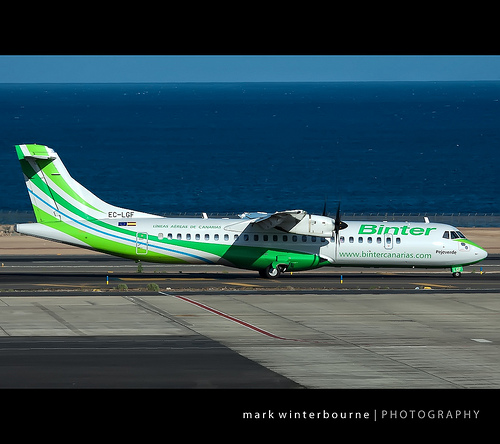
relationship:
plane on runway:
[8, 135, 487, 287] [5, 257, 477, 295]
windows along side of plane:
[152, 223, 403, 251] [8, 135, 487, 287]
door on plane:
[129, 228, 157, 257] [8, 135, 487, 287]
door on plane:
[381, 227, 397, 252] [0, 110, 482, 272]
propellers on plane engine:
[315, 195, 345, 240] [319, 210, 352, 237]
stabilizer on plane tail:
[17, 151, 57, 165] [0, 142, 165, 222]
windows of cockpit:
[434, 224, 464, 239] [425, 215, 484, 271]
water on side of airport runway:
[7, 82, 499, 219] [455, 226, 484, 251]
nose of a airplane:
[467, 239, 484, 269] [3, 135, 474, 279]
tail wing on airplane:
[4, 136, 170, 222] [3, 135, 474, 279]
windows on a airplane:
[148, 229, 406, 245] [3, 135, 474, 279]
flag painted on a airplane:
[113, 217, 140, 229] [3, 135, 474, 279]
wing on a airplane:
[239, 201, 307, 237] [3, 135, 474, 279]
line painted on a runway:
[160, 287, 284, 338] [2, 296, 484, 358]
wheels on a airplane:
[257, 266, 284, 277] [3, 135, 474, 279]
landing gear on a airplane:
[444, 265, 473, 280] [3, 135, 474, 279]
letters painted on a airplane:
[354, 220, 439, 240] [3, 135, 474, 279]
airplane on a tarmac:
[3, 135, 474, 279] [2, 260, 482, 335]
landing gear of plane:
[254, 264, 288, 278] [0, 131, 480, 279]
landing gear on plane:
[447, 263, 468, 282] [8, 135, 487, 287]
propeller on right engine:
[331, 193, 345, 243] [298, 206, 348, 238]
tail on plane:
[14, 133, 137, 216] [8, 135, 487, 287]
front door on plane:
[383, 227, 393, 250] [8, 135, 487, 287]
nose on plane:
[456, 232, 487, 273] [7, 136, 486, 269]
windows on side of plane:
[368, 232, 402, 248] [8, 135, 487, 287]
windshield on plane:
[449, 230, 463, 241] [7, 136, 486, 269]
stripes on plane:
[24, 145, 321, 277] [8, 135, 487, 287]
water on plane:
[1, 81, 498, 234] [7, 136, 486, 269]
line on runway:
[160, 287, 284, 338] [5, 292, 499, 386]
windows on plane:
[2, 139, 491, 287] [157, 229, 406, 245]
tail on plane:
[10, 137, 160, 218] [8, 135, 487, 287]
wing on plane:
[248, 209, 312, 236] [7, 136, 486, 269]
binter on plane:
[358, 220, 437, 244] [8, 135, 487, 287]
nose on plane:
[456, 232, 487, 273] [8, 135, 487, 287]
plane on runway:
[8, 135, 487, 287] [0, 254, 497, 370]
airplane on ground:
[3, 135, 474, 279] [6, 227, 493, 393]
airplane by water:
[3, 135, 474, 279] [7, 82, 499, 219]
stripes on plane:
[5, 131, 319, 273] [8, 135, 487, 287]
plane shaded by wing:
[8, 135, 487, 287] [248, 203, 309, 231]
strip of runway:
[9, 258, 499, 297] [7, 254, 499, 383]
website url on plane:
[335, 247, 435, 264] [8, 135, 487, 287]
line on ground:
[177, 290, 281, 340] [7, 292, 493, 388]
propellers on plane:
[314, 197, 345, 259] [8, 135, 487, 287]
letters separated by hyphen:
[101, 209, 117, 222] [113, 211, 121, 218]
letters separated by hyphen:
[122, 210, 137, 220] [113, 211, 121, 218]